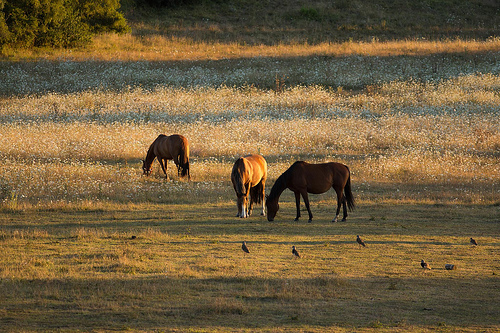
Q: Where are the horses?
A: Natural setting.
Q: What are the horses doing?
A: Eating.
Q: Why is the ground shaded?
A: Trees.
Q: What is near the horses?
A: Birds.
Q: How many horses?
A: Three.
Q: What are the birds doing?
A: Standing on ground.